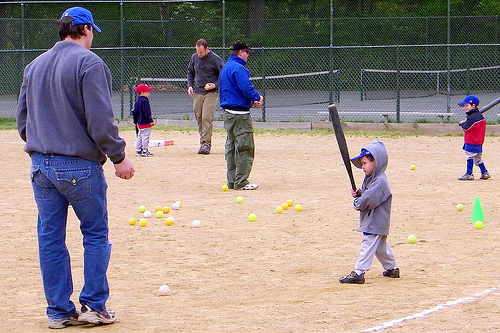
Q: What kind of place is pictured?
A: It is a field.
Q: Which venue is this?
A: This is a field.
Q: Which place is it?
A: It is a field.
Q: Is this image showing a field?
A: Yes, it is showing a field.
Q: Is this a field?
A: Yes, it is a field.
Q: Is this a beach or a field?
A: It is a field.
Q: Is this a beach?
A: No, it is a field.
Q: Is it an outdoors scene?
A: Yes, it is outdoors.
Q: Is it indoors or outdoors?
A: It is outdoors.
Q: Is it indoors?
A: No, it is outdoors.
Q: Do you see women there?
A: No, there are no women.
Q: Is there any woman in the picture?
A: No, there are no women.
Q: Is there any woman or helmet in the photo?
A: No, there are no women or helmets.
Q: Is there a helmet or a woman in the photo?
A: No, there are no women or helmets.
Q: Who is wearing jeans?
A: The man is wearing jeans.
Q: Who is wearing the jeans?
A: The man is wearing jeans.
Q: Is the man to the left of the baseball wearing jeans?
A: Yes, the man is wearing jeans.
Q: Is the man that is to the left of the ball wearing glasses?
A: No, the man is wearing jeans.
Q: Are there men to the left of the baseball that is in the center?
A: Yes, there is a man to the left of the baseball.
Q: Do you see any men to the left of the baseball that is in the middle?
A: Yes, there is a man to the left of the baseball.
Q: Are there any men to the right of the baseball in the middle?
A: No, the man is to the left of the baseball.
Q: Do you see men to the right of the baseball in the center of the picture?
A: No, the man is to the left of the baseball.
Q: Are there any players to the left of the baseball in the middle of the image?
A: No, there is a man to the left of the baseball.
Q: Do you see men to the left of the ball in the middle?
A: Yes, there is a man to the left of the ball.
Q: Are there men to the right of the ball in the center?
A: No, the man is to the left of the ball.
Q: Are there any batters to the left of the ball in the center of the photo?
A: No, there is a man to the left of the ball.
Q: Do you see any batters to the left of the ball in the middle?
A: No, there is a man to the left of the ball.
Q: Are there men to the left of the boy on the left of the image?
A: Yes, there is a man to the left of the boy.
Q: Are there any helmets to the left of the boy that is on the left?
A: No, there is a man to the left of the boy.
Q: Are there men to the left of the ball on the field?
A: Yes, there is a man to the left of the ball.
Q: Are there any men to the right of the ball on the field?
A: No, the man is to the left of the ball.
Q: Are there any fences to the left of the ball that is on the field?
A: No, there is a man to the left of the ball.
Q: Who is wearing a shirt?
A: The man is wearing a shirt.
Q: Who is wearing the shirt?
A: The man is wearing a shirt.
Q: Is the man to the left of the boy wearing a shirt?
A: Yes, the man is wearing a shirt.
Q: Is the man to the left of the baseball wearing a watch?
A: No, the man is wearing a shirt.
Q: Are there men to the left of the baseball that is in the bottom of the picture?
A: Yes, there is a man to the left of the baseball.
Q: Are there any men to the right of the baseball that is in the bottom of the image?
A: No, the man is to the left of the baseball.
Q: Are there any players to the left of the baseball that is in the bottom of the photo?
A: No, there is a man to the left of the baseball.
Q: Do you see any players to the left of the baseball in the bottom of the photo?
A: No, there is a man to the left of the baseball.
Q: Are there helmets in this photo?
A: No, there are no helmets.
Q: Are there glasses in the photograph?
A: No, there are no glasses.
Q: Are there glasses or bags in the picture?
A: No, there are no glasses or bags.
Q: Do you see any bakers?
A: No, there are no bakers.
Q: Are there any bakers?
A: No, there are no bakers.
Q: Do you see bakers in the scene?
A: No, there are no bakers.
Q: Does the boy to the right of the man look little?
A: Yes, the boy is little.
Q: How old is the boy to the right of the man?
A: The boy is little.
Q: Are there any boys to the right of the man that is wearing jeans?
A: Yes, there is a boy to the right of the man.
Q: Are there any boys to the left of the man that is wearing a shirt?
A: No, the boy is to the right of the man.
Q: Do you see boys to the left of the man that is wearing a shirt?
A: No, the boy is to the right of the man.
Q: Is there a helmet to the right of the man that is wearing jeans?
A: No, there is a boy to the right of the man.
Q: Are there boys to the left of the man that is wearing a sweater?
A: Yes, there is a boy to the left of the man.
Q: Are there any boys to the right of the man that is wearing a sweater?
A: No, the boy is to the left of the man.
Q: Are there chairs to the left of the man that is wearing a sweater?
A: No, there is a boy to the left of the man.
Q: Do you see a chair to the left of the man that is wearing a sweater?
A: No, there is a boy to the left of the man.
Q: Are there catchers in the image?
A: No, there are no catchers.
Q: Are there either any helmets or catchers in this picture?
A: No, there are no catchers or helmets.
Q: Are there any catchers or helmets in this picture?
A: No, there are no catchers or helmets.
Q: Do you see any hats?
A: Yes, there is a hat.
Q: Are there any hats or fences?
A: Yes, there is a hat.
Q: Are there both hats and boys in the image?
A: Yes, there are both a hat and a boy.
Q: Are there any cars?
A: No, there are no cars.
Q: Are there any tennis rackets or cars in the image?
A: No, there are no cars or tennis rackets.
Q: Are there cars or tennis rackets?
A: No, there are no cars or tennis rackets.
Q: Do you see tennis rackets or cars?
A: No, there are no cars or tennis rackets.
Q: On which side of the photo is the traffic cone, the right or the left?
A: The traffic cone is on the right of the image.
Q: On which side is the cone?
A: The cone is on the right of the image.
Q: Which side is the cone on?
A: The cone is on the right of the image.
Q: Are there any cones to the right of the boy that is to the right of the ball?
A: Yes, there is a cone to the right of the boy.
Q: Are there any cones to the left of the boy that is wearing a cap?
A: No, the cone is to the right of the boy.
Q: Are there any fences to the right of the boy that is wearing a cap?
A: No, there is a cone to the right of the boy.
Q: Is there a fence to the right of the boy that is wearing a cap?
A: No, there is a cone to the right of the boy.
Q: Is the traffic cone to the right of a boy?
A: Yes, the traffic cone is to the right of a boy.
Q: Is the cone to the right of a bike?
A: No, the cone is to the right of a boy.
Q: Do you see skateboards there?
A: No, there are no skateboards.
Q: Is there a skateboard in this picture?
A: No, there are no skateboards.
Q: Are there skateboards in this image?
A: No, there are no skateboards.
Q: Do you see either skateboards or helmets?
A: No, there are no skateboards or helmets.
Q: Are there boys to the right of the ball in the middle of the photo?
A: Yes, there is a boy to the right of the ball.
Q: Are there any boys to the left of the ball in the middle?
A: No, the boy is to the right of the ball.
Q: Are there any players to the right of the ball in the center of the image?
A: No, there is a boy to the right of the ball.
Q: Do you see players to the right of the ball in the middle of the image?
A: No, there is a boy to the right of the ball.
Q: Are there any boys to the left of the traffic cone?
A: Yes, there is a boy to the left of the traffic cone.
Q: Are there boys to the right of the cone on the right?
A: No, the boy is to the left of the safety cone.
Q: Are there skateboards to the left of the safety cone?
A: No, there is a boy to the left of the safety cone.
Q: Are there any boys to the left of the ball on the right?
A: Yes, there is a boy to the left of the ball.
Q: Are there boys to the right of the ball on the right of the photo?
A: No, the boy is to the left of the ball.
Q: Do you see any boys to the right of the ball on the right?
A: No, the boy is to the left of the ball.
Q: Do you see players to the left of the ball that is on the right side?
A: No, there is a boy to the left of the ball.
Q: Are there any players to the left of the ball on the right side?
A: No, there is a boy to the left of the ball.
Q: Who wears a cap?
A: The boy wears a cap.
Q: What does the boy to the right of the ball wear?
A: The boy wears a cap.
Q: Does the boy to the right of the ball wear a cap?
A: Yes, the boy wears a cap.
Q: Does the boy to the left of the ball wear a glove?
A: No, the boy wears a cap.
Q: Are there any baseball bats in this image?
A: Yes, there is a baseball bat.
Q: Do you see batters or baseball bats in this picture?
A: Yes, there is a baseball bat.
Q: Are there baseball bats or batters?
A: Yes, there is a baseball bat.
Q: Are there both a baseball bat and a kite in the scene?
A: No, there is a baseball bat but no kites.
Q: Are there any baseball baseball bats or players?
A: Yes, there is a baseball baseball bat.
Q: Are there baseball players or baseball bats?
A: Yes, there is a baseball baseball bat.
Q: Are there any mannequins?
A: No, there are no mannequins.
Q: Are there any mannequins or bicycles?
A: No, there are no mannequins or bicycles.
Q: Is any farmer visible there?
A: No, there are no farmers.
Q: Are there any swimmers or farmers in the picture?
A: No, there are no farmers or swimmers.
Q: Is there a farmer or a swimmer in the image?
A: No, there are no farmers or swimmers.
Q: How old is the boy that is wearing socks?
A: The boy is little.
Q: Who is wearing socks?
A: The boy is wearing socks.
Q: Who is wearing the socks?
A: The boy is wearing socks.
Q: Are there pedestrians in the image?
A: No, there are no pedestrians.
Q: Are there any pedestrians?
A: No, there are no pedestrians.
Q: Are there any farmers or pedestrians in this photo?
A: No, there are no pedestrians or farmers.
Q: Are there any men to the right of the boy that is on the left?
A: Yes, there is a man to the right of the boy.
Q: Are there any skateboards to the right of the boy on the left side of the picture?
A: No, there is a man to the right of the boy.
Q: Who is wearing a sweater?
A: The man is wearing a sweater.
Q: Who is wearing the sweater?
A: The man is wearing a sweater.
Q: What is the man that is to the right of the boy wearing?
A: The man is wearing a sweater.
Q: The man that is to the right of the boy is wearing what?
A: The man is wearing a sweater.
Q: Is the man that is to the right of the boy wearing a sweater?
A: Yes, the man is wearing a sweater.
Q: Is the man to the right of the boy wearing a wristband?
A: No, the man is wearing a sweater.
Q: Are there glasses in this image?
A: No, there are no glasses.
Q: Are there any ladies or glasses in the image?
A: No, there are no glasses or ladies.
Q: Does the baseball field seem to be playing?
A: Yes, the field is playing.